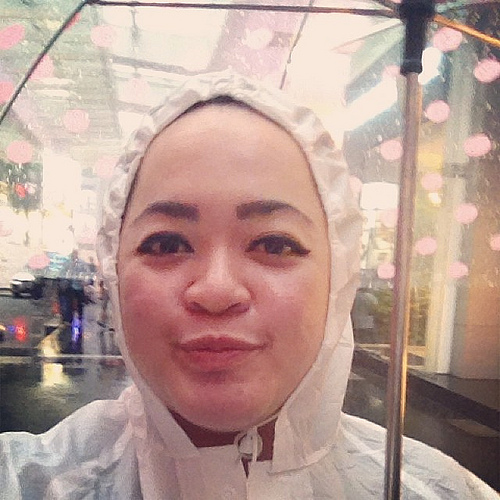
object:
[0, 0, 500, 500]
umbrella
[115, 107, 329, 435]
face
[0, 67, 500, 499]
poncho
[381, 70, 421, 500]
pole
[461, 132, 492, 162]
polka dots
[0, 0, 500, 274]
weather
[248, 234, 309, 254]
eyeliner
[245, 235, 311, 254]
eyelashes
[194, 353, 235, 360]
lipstick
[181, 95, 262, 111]
hairline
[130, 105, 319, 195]
forehead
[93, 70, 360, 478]
hood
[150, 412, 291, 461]
neck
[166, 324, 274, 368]
lips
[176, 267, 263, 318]
nose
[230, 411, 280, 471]
tie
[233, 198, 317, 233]
eyebrow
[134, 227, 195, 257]
eye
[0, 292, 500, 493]
ground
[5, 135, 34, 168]
spots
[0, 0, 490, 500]
day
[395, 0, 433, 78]
knob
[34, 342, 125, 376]
lines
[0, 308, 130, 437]
road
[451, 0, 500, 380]
wall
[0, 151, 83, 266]
lights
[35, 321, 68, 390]
reflection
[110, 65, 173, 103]
light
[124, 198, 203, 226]
eyebrows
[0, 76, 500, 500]
person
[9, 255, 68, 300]
car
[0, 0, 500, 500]
photo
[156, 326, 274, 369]
mouth